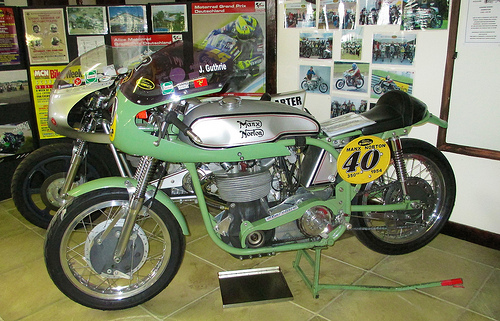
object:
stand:
[291, 247, 466, 301]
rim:
[397, 135, 462, 172]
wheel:
[345, 134, 458, 257]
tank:
[212, 167, 272, 204]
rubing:
[52, 190, 129, 218]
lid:
[220, 162, 235, 173]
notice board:
[261, 0, 460, 166]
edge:
[433, 0, 499, 164]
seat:
[319, 89, 430, 139]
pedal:
[317, 210, 358, 245]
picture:
[283, 3, 317, 29]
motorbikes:
[300, 44, 314, 58]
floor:
[0, 177, 500, 321]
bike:
[41, 38, 460, 312]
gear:
[163, 111, 204, 145]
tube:
[111, 193, 146, 265]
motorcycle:
[41, 39, 463, 313]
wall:
[0, 0, 499, 252]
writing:
[235, 117, 268, 140]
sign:
[188, 1, 277, 102]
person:
[192, 15, 267, 83]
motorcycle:
[7, 38, 446, 233]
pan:
[216, 264, 295, 308]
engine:
[209, 185, 347, 265]